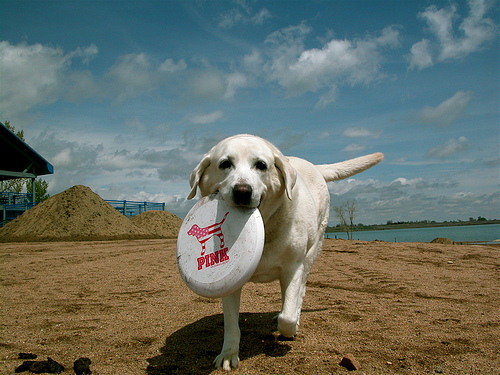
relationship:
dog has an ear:
[186, 133, 384, 372] [275, 145, 293, 199]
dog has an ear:
[186, 133, 384, 372] [187, 150, 209, 200]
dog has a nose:
[186, 133, 384, 372] [232, 182, 253, 199]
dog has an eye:
[186, 133, 384, 372] [218, 157, 232, 171]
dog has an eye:
[186, 133, 384, 372] [253, 158, 267, 170]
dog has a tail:
[186, 133, 384, 372] [312, 152, 384, 181]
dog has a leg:
[186, 133, 384, 372] [276, 260, 304, 337]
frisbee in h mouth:
[175, 194, 265, 300] [215, 185, 267, 209]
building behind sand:
[0, 120, 54, 227] [1, 185, 156, 240]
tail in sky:
[312, 152, 384, 181] [0, 0, 499, 226]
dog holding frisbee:
[186, 133, 384, 372] [175, 194, 265, 300]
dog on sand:
[186, 133, 384, 372] [1, 239, 499, 372]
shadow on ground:
[143, 306, 329, 373] [1, 239, 499, 372]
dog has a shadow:
[186, 133, 384, 372] [143, 306, 329, 373]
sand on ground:
[1, 239, 499, 372] [1, 239, 499, 372]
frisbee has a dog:
[175, 194, 265, 300] [188, 210, 230, 255]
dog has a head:
[186, 133, 384, 372] [187, 133, 298, 223]